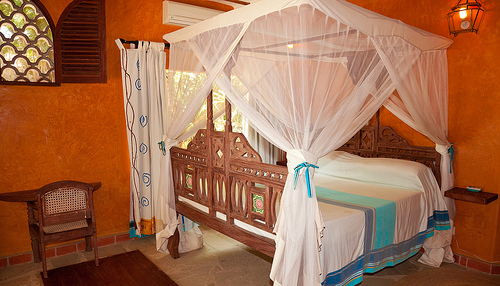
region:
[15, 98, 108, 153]
orange wall paper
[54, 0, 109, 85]
wooden shutter for window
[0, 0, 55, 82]
white design over window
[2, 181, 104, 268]
wooden chair with wooden desk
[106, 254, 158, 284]
wooden slab of floor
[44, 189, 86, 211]
white woven back of chair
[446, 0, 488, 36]
light bulb encased in glass and wood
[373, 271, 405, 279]
floor made form cobblestone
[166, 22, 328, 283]
white, transparent cloth for bed curtains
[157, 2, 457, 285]
A covered bed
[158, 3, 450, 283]
A four poster wooden bed frame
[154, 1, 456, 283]
A shear white bed canapy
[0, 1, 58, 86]
An arched window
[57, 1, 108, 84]
A slated window shutter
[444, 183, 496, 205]
A wooden bed side shelf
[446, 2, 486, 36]
A hanging light fixture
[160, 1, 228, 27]
A white air conditioning unit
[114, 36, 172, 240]
A hanging white curtain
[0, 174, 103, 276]
A wood piece of furniture.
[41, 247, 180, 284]
A brown colored rug.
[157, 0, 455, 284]
White colored bed curtains.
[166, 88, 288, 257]
A brown wood foot board.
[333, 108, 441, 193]
Brown wood headboard.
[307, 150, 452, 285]
Blue and white bedspread.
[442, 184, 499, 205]
Brown wood night table.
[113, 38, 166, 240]
Blue and white curtain.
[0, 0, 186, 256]
An orange colored wall.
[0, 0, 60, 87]
A small intricate window.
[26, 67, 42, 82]
circular piece of glass in window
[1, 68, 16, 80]
circular piece of glass in window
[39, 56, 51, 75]
circular piece of glass in window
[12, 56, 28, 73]
circular piece of glass in window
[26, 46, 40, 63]
circular piece of glass in window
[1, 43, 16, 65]
circular piece of glass in window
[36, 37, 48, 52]
circular piece of glass in window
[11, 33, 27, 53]
circular piece of glass in window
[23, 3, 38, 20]
circular piece of glass in window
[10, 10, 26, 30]
circular piece of glass in window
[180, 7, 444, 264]
the bed drapes are white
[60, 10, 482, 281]
the bed has drapes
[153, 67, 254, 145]
window behind the bed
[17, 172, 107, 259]
the chair is brown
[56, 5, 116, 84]
the window cover is brown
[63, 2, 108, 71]
the cover is wooden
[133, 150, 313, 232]
the bed is brown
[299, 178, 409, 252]
the blanket is many colors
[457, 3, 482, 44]
the light is on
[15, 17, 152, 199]
the walls are orange